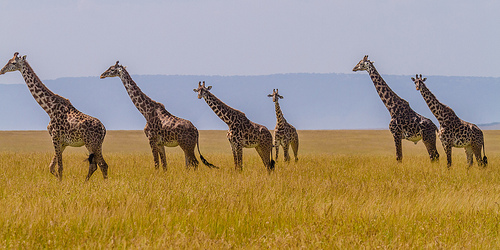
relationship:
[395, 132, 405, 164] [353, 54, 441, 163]
legs of giraffe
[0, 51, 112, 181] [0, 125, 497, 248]
giraffe in field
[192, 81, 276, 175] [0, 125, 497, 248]
giraffe standing in field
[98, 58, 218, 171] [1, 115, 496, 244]
giraffe on field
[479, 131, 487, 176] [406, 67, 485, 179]
tail of giraffe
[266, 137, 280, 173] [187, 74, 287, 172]
tail of giraffe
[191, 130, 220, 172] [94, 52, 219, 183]
tail of giraffe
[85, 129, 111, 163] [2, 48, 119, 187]
tail of giraffe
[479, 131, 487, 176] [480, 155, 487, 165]
tail with tip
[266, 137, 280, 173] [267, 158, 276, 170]
tail with tip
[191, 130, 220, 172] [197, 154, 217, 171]
tail with tip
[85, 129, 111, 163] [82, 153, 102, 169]
tail with tip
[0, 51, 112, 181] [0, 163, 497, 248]
giraffe in field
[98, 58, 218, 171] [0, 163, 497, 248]
giraffe in field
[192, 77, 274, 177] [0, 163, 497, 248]
giraffe in field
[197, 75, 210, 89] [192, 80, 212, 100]
horns on head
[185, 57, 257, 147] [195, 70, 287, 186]
head of giraffe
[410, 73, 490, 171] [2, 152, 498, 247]
giraffe standing in field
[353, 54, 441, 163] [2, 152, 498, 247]
giraffe standing in field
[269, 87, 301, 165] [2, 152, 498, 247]
giraffe standing in field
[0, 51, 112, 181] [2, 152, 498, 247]
giraffe standing in field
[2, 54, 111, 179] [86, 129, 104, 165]
giraffe has a tail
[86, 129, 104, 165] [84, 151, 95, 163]
tail has a tip